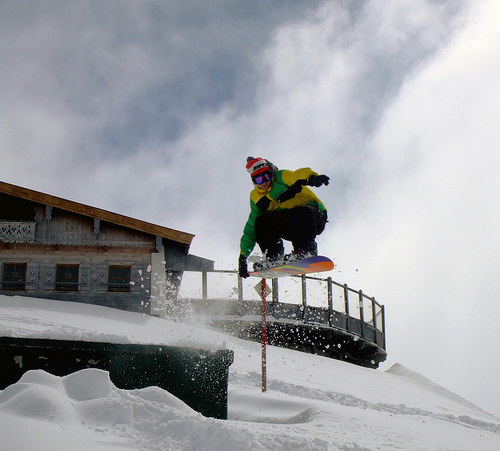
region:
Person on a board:
[239, 251, 344, 283]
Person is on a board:
[240, 250, 340, 282]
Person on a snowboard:
[241, 255, 339, 287]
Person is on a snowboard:
[232, 250, 338, 282]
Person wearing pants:
[247, 203, 325, 255]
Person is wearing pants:
[250, 203, 330, 251]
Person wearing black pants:
[252, 205, 329, 255]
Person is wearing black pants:
[245, 206, 326, 248]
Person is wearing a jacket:
[230, 165, 335, 264]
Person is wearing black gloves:
[233, 166, 333, 284]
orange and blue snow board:
[245, 255, 335, 278]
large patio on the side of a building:
[176, 268, 386, 366]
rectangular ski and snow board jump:
[0, 333, 235, 420]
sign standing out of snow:
[253, 278, 271, 390]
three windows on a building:
[1, 260, 131, 292]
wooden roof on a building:
[0, 180, 195, 255]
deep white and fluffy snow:
[1, 293, 498, 450]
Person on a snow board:
[237, 156, 335, 277]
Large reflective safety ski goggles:
[251, 170, 275, 185]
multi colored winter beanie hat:
[244, 154, 269, 175]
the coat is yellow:
[288, 172, 302, 179]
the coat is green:
[245, 227, 253, 241]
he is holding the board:
[233, 261, 258, 281]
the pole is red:
[258, 300, 272, 319]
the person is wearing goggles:
[249, 174, 276, 184]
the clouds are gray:
[74, 21, 113, 62]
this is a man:
[231, 201, 249, 269]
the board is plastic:
[246, 253, 313, 323]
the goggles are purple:
[224, 161, 284, 193]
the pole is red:
[233, 319, 289, 390]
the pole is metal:
[241, 304, 298, 389]